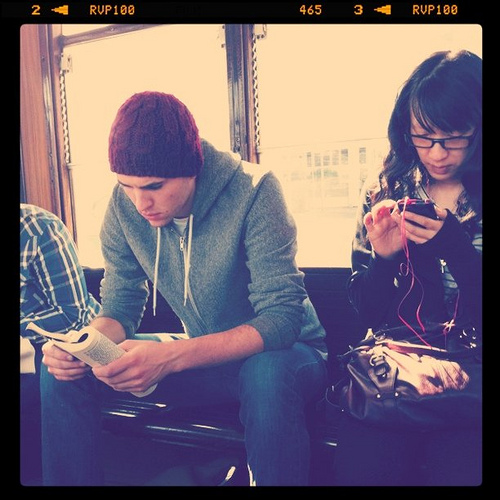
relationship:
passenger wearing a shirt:
[5, 204, 94, 485] [17, 204, 99, 345]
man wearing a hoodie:
[38, 89, 330, 484] [82, 134, 338, 356]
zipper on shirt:
[179, 238, 184, 250] [95, 137, 330, 349]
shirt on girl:
[347, 47, 480, 475] [345, 47, 487, 404]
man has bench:
[38, 89, 330, 484] [263, 241, 378, 368]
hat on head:
[107, 89, 205, 178] [99, 82, 224, 241]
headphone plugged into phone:
[400, 192, 419, 207] [394, 190, 424, 246]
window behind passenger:
[59, 25, 231, 267] [5, 204, 94, 485]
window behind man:
[59, 25, 231, 267] [38, 89, 330, 484]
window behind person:
[59, 25, 231, 267] [335, 48, 484, 486]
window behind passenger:
[251, 24, 481, 268] [5, 204, 94, 485]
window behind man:
[251, 24, 481, 268] [38, 89, 330, 484]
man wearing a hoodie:
[38, 89, 330, 484] [94, 138, 328, 351]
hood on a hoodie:
[184, 137, 244, 235] [94, 138, 328, 351]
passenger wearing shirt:
[5, 204, 94, 485] [12, 196, 109, 371]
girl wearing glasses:
[345, 47, 487, 404] [393, 127, 476, 157]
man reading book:
[38, 89, 330, 484] [21, 298, 161, 398]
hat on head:
[107, 89, 205, 178] [114, 92, 204, 227]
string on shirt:
[182, 209, 192, 305] [95, 137, 330, 349]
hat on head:
[94, 97, 204, 168] [91, 97, 222, 231]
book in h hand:
[27, 321, 159, 398] [90, 337, 160, 392]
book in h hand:
[27, 321, 159, 398] [40, 339, 90, 380]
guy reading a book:
[105, 92, 293, 372] [31, 325, 155, 405]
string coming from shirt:
[151, 223, 161, 315] [95, 137, 330, 349]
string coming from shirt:
[182, 209, 192, 305] [95, 137, 330, 349]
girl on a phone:
[337, 69, 487, 404] [380, 193, 434, 254]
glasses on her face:
[401, 127, 476, 150] [407, 102, 479, 181]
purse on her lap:
[328, 325, 478, 430] [327, 388, 479, 446]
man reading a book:
[38, 89, 330, 484] [36, 303, 176, 404]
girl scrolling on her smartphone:
[345, 47, 487, 404] [392, 193, 441, 231]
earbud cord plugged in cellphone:
[400, 197, 460, 349] [397, 198, 438, 221]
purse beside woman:
[328, 325, 478, 430] [330, 50, 480, 484]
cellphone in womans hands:
[397, 198, 438, 221] [352, 190, 463, 257]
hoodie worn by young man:
[94, 138, 328, 351] [38, 89, 330, 484]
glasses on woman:
[399, 122, 474, 162] [367, 48, 484, 232]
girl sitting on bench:
[345, 47, 487, 404] [81, 267, 487, 487]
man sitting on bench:
[38, 89, 330, 484] [81, 267, 487, 487]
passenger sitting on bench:
[19, 202, 106, 485] [81, 267, 487, 487]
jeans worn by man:
[31, 325, 333, 486] [38, 89, 330, 484]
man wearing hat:
[38, 89, 330, 484] [107, 89, 205, 178]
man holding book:
[38, 89, 330, 484] [33, 322, 151, 400]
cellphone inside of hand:
[407, 199, 440, 220] [397, 205, 447, 252]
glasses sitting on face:
[401, 127, 476, 150] [402, 113, 466, 187]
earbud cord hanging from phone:
[400, 201, 457, 349] [400, 200, 447, 257]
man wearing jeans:
[38, 89, 330, 484] [37, 325, 328, 485]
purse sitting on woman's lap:
[328, 325, 478, 430] [330, 44, 475, 474]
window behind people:
[59, 25, 227, 262] [83, 49, 498, 449]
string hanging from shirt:
[439, 288, 462, 330] [365, 181, 412, 200]